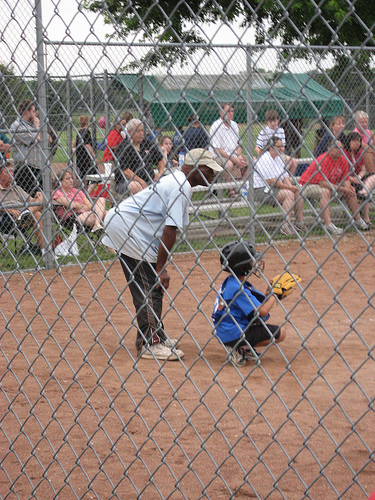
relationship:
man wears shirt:
[102, 147, 218, 363] [103, 169, 188, 257]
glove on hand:
[263, 271, 303, 301] [271, 279, 289, 297]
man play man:
[102, 147, 218, 363] [102, 147, 218, 363]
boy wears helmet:
[209, 238, 305, 367] [217, 237, 264, 278]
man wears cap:
[102, 147, 218, 363] [182, 147, 222, 169]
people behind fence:
[1, 95, 374, 254] [3, 1, 373, 498]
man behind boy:
[102, 147, 218, 363] [210, 240, 304, 367]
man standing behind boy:
[84, 120, 219, 471] [210, 240, 304, 367]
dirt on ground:
[1, 229, 373, 499] [1, 232, 372, 499]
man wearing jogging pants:
[102, 147, 218, 363] [131, 288, 209, 353]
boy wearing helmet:
[209, 238, 305, 367] [220, 236, 267, 280]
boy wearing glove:
[209, 238, 305, 367] [267, 265, 303, 301]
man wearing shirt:
[299, 140, 368, 235] [307, 149, 343, 181]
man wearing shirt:
[212, 100, 247, 193] [206, 115, 241, 164]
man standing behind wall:
[102, 147, 218, 363] [160, 51, 211, 62]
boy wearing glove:
[209, 238, 305, 367] [265, 273, 305, 302]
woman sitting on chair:
[35, 147, 137, 254] [39, 204, 93, 245]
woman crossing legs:
[51, 168, 114, 253] [76, 197, 114, 253]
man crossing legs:
[1, 161, 47, 253] [12, 198, 44, 255]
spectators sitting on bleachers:
[6, 100, 374, 218] [182, 167, 365, 230]